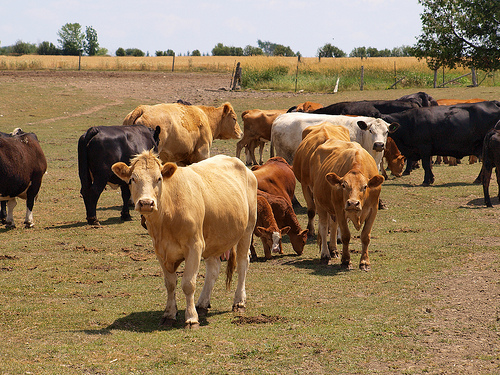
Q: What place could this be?
A: It is a field.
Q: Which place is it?
A: It is a field.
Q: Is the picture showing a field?
A: Yes, it is showing a field.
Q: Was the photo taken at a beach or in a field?
A: It was taken at a field.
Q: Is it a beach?
A: No, it is a field.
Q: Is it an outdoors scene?
A: Yes, it is outdoors.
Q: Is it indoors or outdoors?
A: It is outdoors.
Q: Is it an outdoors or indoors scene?
A: It is outdoors.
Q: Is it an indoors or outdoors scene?
A: It is outdoors.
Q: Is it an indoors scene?
A: No, it is outdoors.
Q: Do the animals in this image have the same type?
A: Yes, all the animals are cows.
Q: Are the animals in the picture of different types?
A: No, all the animals are cows.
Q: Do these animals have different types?
A: No, all the animals are cows.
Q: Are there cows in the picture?
A: Yes, there is a cow.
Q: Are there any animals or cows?
A: Yes, there is a cow.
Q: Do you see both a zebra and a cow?
A: No, there is a cow but no zebras.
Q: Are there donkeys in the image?
A: No, there are no donkeys.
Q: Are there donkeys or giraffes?
A: No, there are no donkeys or giraffes.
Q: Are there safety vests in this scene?
A: No, there are no safety vests.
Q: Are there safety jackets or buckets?
A: No, there are no safety jackets or buckets.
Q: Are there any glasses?
A: No, there are no glasses.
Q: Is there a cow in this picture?
A: Yes, there is a cow.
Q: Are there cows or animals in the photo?
A: Yes, there is a cow.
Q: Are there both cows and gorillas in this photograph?
A: No, there is a cow but no gorillas.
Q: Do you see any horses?
A: No, there are no horses.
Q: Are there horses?
A: No, there are no horses.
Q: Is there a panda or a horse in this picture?
A: No, there are no horses or pandas.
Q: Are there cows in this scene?
A: Yes, there is a cow.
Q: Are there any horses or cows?
A: Yes, there is a cow.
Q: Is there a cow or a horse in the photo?
A: Yes, there is a cow.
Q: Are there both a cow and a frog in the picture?
A: No, there is a cow but no frogs.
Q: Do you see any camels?
A: No, there are no camels.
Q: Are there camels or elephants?
A: No, there are no camels or elephants.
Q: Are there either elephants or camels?
A: No, there are no camels or elephants.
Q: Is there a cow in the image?
A: Yes, there is a cow.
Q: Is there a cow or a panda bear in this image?
A: Yes, there is a cow.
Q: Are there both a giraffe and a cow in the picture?
A: No, there is a cow but no giraffes.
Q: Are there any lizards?
A: No, there are no lizards.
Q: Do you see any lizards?
A: No, there are no lizards.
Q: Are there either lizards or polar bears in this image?
A: No, there are no lizards or polar bears.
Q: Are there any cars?
A: No, there are no cars.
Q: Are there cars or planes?
A: No, there are no cars or planes.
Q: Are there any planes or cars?
A: No, there are no cars or planes.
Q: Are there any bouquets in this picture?
A: No, there are no bouquets.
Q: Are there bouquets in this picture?
A: No, there are no bouquets.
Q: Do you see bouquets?
A: No, there are no bouquets.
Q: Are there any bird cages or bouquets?
A: No, there are no bouquets or bird cages.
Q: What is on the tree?
A: The leaves are on the tree.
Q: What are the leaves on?
A: The leaves are on the tree.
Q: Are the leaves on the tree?
A: Yes, the leaves are on the tree.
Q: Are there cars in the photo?
A: No, there are no cars.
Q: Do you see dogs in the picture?
A: No, there are no dogs.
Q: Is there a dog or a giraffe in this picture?
A: No, there are no dogs or giraffes.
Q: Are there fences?
A: Yes, there is a fence.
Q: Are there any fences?
A: Yes, there is a fence.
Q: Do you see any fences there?
A: Yes, there is a fence.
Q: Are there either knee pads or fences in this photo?
A: Yes, there is a fence.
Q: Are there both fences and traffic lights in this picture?
A: No, there is a fence but no traffic lights.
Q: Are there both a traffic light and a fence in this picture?
A: No, there is a fence but no traffic lights.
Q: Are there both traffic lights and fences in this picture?
A: No, there is a fence but no traffic lights.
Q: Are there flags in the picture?
A: No, there are no flags.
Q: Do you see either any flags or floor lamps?
A: No, there are no flags or floor lamps.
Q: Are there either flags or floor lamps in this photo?
A: No, there are no flags or floor lamps.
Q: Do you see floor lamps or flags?
A: No, there are no flags or floor lamps.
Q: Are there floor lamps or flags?
A: No, there are no flags or floor lamps.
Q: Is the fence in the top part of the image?
A: Yes, the fence is in the top of the image.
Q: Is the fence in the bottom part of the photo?
A: No, the fence is in the top of the image.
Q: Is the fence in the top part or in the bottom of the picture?
A: The fence is in the top of the image.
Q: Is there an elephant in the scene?
A: No, there are no elephants.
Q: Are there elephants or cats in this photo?
A: No, there are no elephants or cats.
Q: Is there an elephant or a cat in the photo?
A: No, there are no elephants or cats.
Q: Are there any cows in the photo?
A: Yes, there are cows.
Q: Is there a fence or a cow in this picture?
A: Yes, there are cows.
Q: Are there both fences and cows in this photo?
A: Yes, there are both cows and a fence.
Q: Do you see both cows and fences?
A: Yes, there are both cows and a fence.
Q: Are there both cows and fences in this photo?
A: Yes, there are both cows and a fence.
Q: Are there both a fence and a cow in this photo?
A: Yes, there are both a cow and a fence.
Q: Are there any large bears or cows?
A: Yes, there are large cows.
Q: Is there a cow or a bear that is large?
A: Yes, the cows are large.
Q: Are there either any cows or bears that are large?
A: Yes, the cows are large.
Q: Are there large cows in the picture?
A: Yes, there are large cows.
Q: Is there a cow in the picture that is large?
A: Yes, there are cows that are large.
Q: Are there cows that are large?
A: Yes, there are cows that are large.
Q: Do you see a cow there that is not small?
A: Yes, there are large cows.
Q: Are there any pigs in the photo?
A: No, there are no pigs.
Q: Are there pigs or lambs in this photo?
A: No, there are no pigs or lambs.